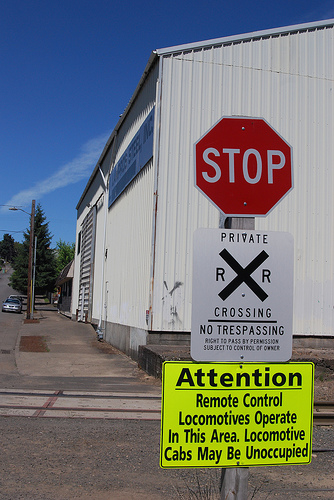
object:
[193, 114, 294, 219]
sign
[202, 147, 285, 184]
stop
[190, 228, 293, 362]
sign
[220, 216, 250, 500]
post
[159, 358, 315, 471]
sign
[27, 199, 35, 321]
pole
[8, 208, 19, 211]
light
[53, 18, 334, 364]
building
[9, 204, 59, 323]
tree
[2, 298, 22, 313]
car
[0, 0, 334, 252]
sky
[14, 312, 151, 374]
sidewalk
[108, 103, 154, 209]
sign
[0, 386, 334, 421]
track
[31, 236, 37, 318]
pole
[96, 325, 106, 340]
meter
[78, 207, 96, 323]
door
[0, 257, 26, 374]
street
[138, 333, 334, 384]
concrete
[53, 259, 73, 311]
store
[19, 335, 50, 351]
section